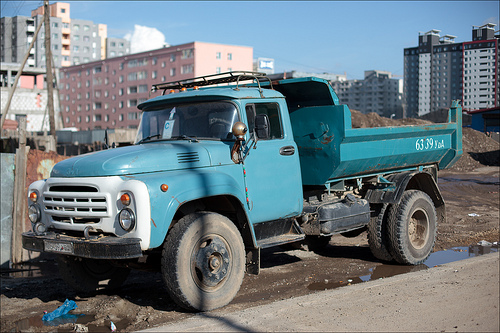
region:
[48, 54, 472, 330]
a blue old truck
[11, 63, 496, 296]
the tipper is parked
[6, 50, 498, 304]
the truck is loaded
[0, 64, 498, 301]
its blue in colour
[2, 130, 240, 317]
its bumper is white in colour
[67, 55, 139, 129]
a red painted house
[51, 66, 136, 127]
the house has windows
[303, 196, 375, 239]
the tank is black in colour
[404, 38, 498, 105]
the wall is grey in colour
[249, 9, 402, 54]
the sky is blue and clear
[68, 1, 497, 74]
blue of daytime sky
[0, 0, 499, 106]
city buildings on horizon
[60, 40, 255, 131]
red building with flat roof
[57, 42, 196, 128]
windows on side of building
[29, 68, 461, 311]
side of dump truck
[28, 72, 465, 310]
side and front of truck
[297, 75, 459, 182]
dirt in truck bet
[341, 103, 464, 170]
white number on blue bed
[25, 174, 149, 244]
white grill on old truck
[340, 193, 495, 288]
water puddle under tires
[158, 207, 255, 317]
Left front tire of old blue truck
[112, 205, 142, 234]
Left front headlight of old blue truck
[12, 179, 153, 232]
white front grill of old blue truck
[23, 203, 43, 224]
Right front tire of old blue truck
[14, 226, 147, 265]
black front bumper of old blue truck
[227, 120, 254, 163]
Left front mirror of old blue truck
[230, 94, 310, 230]
Left front door of old blue truck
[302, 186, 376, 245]
Black gas tank on blue truck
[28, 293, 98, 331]
Blue bag in puddle on ground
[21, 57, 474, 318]
Blue dump truck parked in dirt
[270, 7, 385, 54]
this is the sky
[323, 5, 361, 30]
the sky is blue in color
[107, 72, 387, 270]
this is a lorry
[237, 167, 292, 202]
the lorry is blue in color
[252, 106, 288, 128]
this is the window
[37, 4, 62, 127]
this is a pole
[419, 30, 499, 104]
this is a building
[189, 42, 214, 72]
this is a wall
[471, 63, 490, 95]
the wall is white in color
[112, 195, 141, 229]
this is the head lump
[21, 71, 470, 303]
a light blue truck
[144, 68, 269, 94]
a metal roof rack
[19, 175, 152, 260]
a white metal truck grill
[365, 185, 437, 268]
a pair of large tires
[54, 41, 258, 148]
a long brick building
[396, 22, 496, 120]
a tall apartment building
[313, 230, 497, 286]
a puddle in the dirt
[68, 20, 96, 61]
a few square windows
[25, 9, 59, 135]
a wood structure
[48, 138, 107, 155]
the top of a wood fence